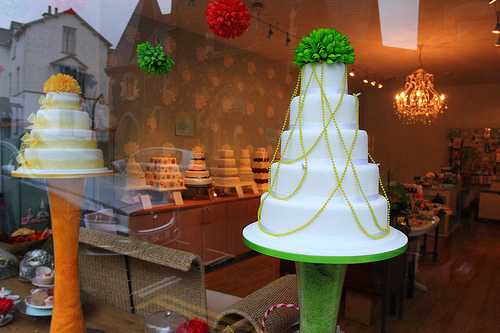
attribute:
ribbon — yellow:
[40, 73, 82, 93]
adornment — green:
[130, 41, 182, 73]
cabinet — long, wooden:
[129, 186, 311, 289]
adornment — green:
[293, 26, 357, 63]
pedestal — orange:
[11, 160, 128, 332]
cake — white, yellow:
[12, 91, 109, 175]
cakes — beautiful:
[142, 144, 271, 190]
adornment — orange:
[40, 72, 82, 94]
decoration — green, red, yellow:
[41, 70, 83, 95]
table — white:
[409, 218, 441, 293]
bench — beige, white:
[99, 224, 262, 325]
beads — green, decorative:
[313, 65, 338, 136]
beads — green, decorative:
[331, 149, 363, 206]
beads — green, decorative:
[353, 201, 391, 238]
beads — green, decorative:
[286, 72, 306, 159]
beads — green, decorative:
[263, 158, 308, 201]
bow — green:
[293, 25, 362, 71]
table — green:
[241, 221, 410, 331]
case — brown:
[142, 198, 254, 257]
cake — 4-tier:
[9, 70, 115, 179]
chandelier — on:
[367, 50, 457, 138]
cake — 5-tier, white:
[254, 64, 391, 245]